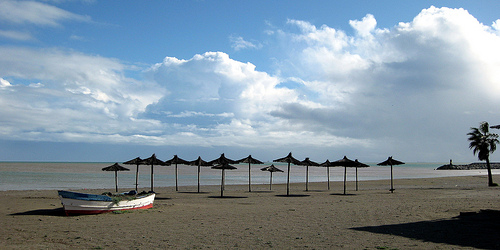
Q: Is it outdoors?
A: Yes, it is outdoors.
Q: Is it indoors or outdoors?
A: It is outdoors.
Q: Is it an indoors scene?
A: No, it is outdoors.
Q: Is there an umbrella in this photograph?
A: Yes, there is an umbrella.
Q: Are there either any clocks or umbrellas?
A: Yes, there is an umbrella.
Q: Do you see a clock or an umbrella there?
A: Yes, there is an umbrella.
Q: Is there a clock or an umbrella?
A: Yes, there is an umbrella.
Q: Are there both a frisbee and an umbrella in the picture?
A: No, there is an umbrella but no frisbees.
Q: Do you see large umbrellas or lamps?
A: Yes, there is a large umbrella.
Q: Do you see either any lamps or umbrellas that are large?
A: Yes, the umbrella is large.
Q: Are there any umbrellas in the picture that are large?
A: Yes, there is an umbrella that is large.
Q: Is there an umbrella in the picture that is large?
A: Yes, there is an umbrella that is large.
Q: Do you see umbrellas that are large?
A: Yes, there is an umbrella that is large.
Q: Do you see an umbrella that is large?
A: Yes, there is an umbrella that is large.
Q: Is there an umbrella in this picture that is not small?
A: Yes, there is a large umbrella.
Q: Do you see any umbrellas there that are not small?
A: Yes, there is a large umbrella.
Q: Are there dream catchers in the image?
A: No, there are no dream catchers.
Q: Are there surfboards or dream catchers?
A: No, there are no dream catchers or surfboards.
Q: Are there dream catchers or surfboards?
A: No, there are no dream catchers or surfboards.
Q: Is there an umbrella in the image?
A: Yes, there is an umbrella.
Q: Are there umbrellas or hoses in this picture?
A: Yes, there is an umbrella.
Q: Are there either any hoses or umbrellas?
A: Yes, there is an umbrella.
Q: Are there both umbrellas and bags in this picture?
A: No, there is an umbrella but no bags.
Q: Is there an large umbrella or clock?
A: Yes, there is a large umbrella.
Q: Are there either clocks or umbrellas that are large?
A: Yes, the umbrella is large.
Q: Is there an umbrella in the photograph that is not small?
A: Yes, there is a large umbrella.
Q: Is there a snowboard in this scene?
A: No, there are no snowboards.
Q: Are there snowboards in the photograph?
A: No, there are no snowboards.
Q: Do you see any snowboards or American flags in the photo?
A: No, there are no snowboards or American flags.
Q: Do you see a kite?
A: No, there are no kites.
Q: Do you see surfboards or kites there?
A: No, there are no kites or surfboards.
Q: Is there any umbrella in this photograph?
A: Yes, there is an umbrella.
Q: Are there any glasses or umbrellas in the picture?
A: Yes, there is an umbrella.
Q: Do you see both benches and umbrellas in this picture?
A: No, there is an umbrella but no benches.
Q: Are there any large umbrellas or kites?
A: Yes, there is a large umbrella.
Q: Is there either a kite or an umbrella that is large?
A: Yes, the umbrella is large.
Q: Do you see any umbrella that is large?
A: Yes, there is a large umbrella.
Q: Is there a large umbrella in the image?
A: Yes, there is a large umbrella.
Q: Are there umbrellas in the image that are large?
A: Yes, there is a large umbrella.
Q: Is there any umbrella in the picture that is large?
A: Yes, there is an umbrella that is large.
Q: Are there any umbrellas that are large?
A: Yes, there is an umbrella that is large.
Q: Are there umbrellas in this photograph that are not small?
A: Yes, there is a large umbrella.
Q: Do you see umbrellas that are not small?
A: Yes, there is a large umbrella.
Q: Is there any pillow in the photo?
A: No, there are no pillows.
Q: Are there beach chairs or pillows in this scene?
A: No, there are no pillows or beach chairs.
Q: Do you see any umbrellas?
A: Yes, there is an umbrella.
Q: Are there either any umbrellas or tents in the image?
A: Yes, there is an umbrella.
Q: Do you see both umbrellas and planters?
A: No, there is an umbrella but no planters.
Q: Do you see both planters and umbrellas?
A: No, there is an umbrella but no planters.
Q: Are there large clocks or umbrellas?
A: Yes, there is a large umbrella.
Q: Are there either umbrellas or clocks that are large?
A: Yes, the umbrella is large.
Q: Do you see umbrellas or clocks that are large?
A: Yes, the umbrella is large.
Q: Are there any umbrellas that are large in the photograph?
A: Yes, there is a large umbrella.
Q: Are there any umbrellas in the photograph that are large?
A: Yes, there is an umbrella that is large.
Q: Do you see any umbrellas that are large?
A: Yes, there is an umbrella that is large.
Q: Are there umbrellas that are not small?
A: Yes, there is a large umbrella.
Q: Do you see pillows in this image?
A: No, there are no pillows.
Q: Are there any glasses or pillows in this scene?
A: No, there are no pillows or glasses.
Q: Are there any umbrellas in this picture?
A: Yes, there is an umbrella.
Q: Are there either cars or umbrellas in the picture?
A: Yes, there is an umbrella.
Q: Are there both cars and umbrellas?
A: No, there is an umbrella but no cars.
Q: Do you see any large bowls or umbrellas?
A: Yes, there is a large umbrella.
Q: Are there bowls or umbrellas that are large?
A: Yes, the umbrella is large.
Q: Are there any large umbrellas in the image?
A: Yes, there is a large umbrella.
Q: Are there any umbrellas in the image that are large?
A: Yes, there is a large umbrella.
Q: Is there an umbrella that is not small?
A: Yes, there is a large umbrella.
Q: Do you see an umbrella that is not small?
A: Yes, there is a large umbrella.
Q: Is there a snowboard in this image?
A: No, there are no snowboards.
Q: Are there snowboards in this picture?
A: No, there are no snowboards.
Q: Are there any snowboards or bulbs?
A: No, there are no snowboards or bulbs.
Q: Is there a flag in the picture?
A: No, there are no flags.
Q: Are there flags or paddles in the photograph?
A: No, there are no flags or paddles.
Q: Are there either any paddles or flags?
A: No, there are no flags or paddles.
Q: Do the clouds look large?
A: Yes, the clouds are large.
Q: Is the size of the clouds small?
A: No, the clouds are large.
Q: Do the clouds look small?
A: No, the clouds are large.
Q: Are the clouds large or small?
A: The clouds are large.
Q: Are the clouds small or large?
A: The clouds are large.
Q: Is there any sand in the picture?
A: Yes, there is sand.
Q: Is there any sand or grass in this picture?
A: Yes, there is sand.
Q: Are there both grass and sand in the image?
A: No, there is sand but no grass.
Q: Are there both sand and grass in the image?
A: No, there is sand but no grass.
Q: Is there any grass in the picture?
A: No, there is no grass.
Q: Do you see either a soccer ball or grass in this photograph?
A: No, there are no grass or soccer balls.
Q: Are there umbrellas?
A: Yes, there is an umbrella.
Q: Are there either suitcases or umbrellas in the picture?
A: Yes, there is an umbrella.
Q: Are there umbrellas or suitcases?
A: Yes, there is an umbrella.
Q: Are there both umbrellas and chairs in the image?
A: No, there is an umbrella but no chairs.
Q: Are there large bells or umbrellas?
A: Yes, there is a large umbrella.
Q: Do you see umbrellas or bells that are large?
A: Yes, the umbrella is large.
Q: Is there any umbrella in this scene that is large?
A: Yes, there is an umbrella that is large.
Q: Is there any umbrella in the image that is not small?
A: Yes, there is a large umbrella.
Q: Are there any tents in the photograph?
A: No, there are no tents.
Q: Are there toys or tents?
A: No, there are no tents or toys.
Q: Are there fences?
A: No, there are no fences.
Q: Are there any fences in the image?
A: No, there are no fences.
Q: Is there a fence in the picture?
A: No, there are no fences.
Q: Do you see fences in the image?
A: No, there are no fences.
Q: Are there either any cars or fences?
A: No, there are no fences or cars.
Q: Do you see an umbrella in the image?
A: Yes, there is an umbrella.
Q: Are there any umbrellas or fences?
A: Yes, there is an umbrella.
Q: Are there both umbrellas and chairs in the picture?
A: No, there is an umbrella but no chairs.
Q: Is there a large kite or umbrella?
A: Yes, there is a large umbrella.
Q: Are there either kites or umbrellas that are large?
A: Yes, the umbrella is large.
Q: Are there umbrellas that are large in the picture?
A: Yes, there is a large umbrella.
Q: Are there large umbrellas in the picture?
A: Yes, there is a large umbrella.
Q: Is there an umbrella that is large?
A: Yes, there is an umbrella that is large.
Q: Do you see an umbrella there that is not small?
A: Yes, there is a large umbrella.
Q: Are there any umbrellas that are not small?
A: Yes, there is a large umbrella.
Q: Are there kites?
A: No, there are no kites.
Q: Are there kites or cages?
A: No, there are no kites or cages.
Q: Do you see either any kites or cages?
A: No, there are no kites or cages.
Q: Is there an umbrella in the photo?
A: Yes, there is an umbrella.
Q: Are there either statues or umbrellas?
A: Yes, there is an umbrella.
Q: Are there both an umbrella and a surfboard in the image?
A: No, there is an umbrella but no surfboards.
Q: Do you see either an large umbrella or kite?
A: Yes, there is a large umbrella.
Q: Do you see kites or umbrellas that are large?
A: Yes, the umbrella is large.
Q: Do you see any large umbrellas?
A: Yes, there is a large umbrella.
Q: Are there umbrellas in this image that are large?
A: Yes, there is an umbrella that is large.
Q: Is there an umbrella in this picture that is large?
A: Yes, there is an umbrella that is large.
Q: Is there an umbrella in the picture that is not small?
A: Yes, there is a large umbrella.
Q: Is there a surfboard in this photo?
A: No, there are no surfboards.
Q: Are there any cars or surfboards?
A: No, there are no surfboards or cars.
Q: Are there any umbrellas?
A: Yes, there is an umbrella.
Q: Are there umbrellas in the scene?
A: Yes, there is an umbrella.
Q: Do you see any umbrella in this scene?
A: Yes, there is an umbrella.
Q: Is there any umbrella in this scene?
A: Yes, there is an umbrella.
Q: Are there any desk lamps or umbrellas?
A: Yes, there is an umbrella.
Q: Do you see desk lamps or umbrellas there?
A: Yes, there is an umbrella.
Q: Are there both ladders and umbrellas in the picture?
A: No, there is an umbrella but no ladders.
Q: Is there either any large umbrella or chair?
A: Yes, there is a large umbrella.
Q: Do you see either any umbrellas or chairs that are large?
A: Yes, the umbrella is large.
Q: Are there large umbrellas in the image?
A: Yes, there is a large umbrella.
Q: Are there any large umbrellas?
A: Yes, there is a large umbrella.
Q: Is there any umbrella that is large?
A: Yes, there is an umbrella that is large.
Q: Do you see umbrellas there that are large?
A: Yes, there is an umbrella that is large.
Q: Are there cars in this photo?
A: No, there are no cars.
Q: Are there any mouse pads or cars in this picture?
A: No, there are no cars or mouse pads.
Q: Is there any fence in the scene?
A: No, there are no fences.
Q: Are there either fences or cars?
A: No, there are no fences or cars.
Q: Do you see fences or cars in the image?
A: No, there are no fences or cars.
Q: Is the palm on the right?
A: Yes, the palm is on the right of the image.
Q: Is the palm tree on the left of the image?
A: No, the palm tree is on the right of the image.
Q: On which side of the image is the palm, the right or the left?
A: The palm is on the right of the image.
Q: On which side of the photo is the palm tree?
A: The palm tree is on the right of the image.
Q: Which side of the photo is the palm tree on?
A: The palm tree is on the right of the image.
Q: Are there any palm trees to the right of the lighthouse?
A: Yes, there is a palm tree to the right of the lighthouse.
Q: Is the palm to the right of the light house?
A: Yes, the palm is to the right of the light house.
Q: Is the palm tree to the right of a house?
A: No, the palm tree is to the right of the light house.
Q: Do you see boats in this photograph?
A: Yes, there is a boat.